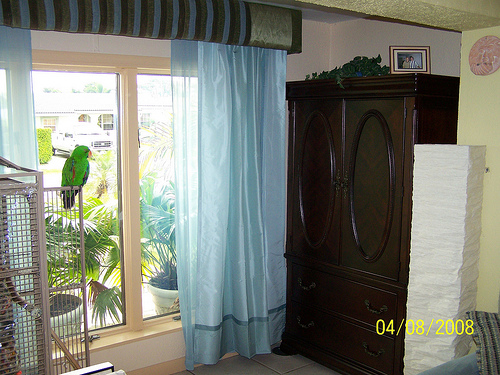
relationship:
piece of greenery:
[87, 279, 126, 329] [41, 196, 126, 328]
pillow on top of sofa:
[462, 310, 499, 375] [419, 354, 482, 375]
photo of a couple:
[391, 44, 433, 76] [401, 56, 423, 71]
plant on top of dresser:
[306, 55, 393, 90] [278, 70, 462, 374]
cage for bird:
[0, 155, 90, 374] [56, 145, 94, 209]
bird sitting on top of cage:
[56, 145, 94, 209] [0, 155, 90, 374]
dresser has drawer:
[278, 70, 462, 374] [288, 258, 402, 332]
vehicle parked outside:
[51, 118, 117, 160] [2, 70, 198, 337]